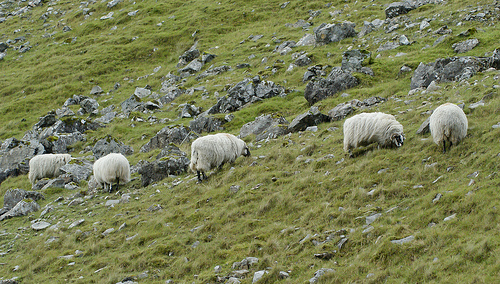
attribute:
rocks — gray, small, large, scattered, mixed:
[22, 18, 500, 181]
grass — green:
[0, 0, 499, 282]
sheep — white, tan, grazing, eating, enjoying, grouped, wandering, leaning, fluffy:
[25, 82, 475, 187]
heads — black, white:
[229, 136, 409, 159]